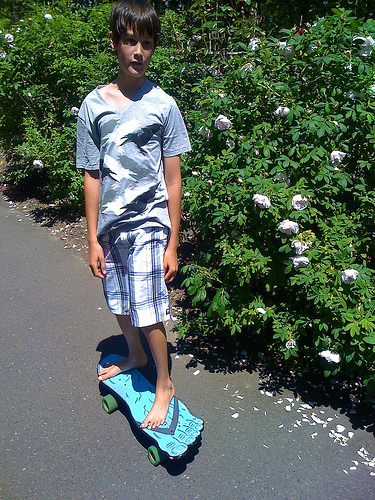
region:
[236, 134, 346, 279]
white flowers on a green bush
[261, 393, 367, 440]
flower petals on ground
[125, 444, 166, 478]
green wheel on skateboard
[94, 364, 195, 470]
green skate board that is shaped like a foot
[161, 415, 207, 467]
toes of a fake foot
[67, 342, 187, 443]
2 feet on a skate board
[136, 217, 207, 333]
blue and white shorts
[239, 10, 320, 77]
red flower on bush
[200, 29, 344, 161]
red and white flower on bush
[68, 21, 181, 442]
boy riding a skate board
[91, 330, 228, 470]
a blue skateboard with a foot design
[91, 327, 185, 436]
bare feet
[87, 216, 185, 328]
blue and white plaid shorts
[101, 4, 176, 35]
black hair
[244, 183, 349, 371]
some white flowers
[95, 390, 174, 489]
green wheels on the ground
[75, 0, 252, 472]
a boy riding a skateboard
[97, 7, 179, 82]
a cool facial expression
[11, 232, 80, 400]
a black paved road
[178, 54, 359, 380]
a big green bush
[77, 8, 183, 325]
boy in blue plaid shorts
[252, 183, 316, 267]
white flowers in a green bush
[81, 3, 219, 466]
boy skateboarding barefoot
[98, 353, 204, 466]
skateboard is blue with green wheels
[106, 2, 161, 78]
boy has brown hair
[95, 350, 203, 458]
skateboard shaped like a giant foot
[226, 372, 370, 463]
petals in the road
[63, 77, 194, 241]
blue v-neck shirt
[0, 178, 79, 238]
shadow cast on the ground by the bushes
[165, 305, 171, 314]
logo on boy's shorts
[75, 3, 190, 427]
Young boy skateboarding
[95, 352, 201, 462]
Blue skateboard shaped like foot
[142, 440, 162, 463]
Green wheel on skateboard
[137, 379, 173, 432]
Bare foot of boy skateboarder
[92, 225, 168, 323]
Blue and white striped shorts on boy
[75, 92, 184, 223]
Gray and white shirt on boy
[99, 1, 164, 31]
Brown hair of young boy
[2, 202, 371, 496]
Paved path for skateboarder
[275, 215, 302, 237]
White flower on green shrubbery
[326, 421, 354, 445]
Flower petals on path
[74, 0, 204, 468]
A little white boy riding a skateboard.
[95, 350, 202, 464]
A blue skateboard shaped like a foot.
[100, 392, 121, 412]
One of the green tires of the skateboard.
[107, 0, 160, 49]
The hair of a handsome little boy.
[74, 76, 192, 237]
A grey shirt with a strange design.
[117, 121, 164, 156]
The drawing of a black crow.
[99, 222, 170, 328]
The boy is wearing very casual shorts.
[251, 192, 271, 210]
A pink flower near the young boy.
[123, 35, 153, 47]
The eyes of a cute little boy.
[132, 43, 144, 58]
The nose of a little boy.